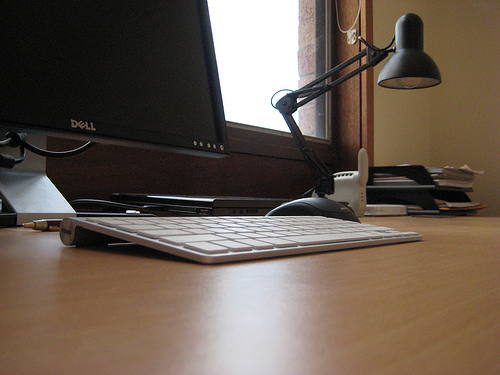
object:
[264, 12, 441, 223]
lamp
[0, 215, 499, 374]
desk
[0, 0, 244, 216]
computer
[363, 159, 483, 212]
rack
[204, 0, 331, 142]
window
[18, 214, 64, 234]
pen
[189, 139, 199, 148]
button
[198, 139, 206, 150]
button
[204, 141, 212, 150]
button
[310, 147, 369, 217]
modem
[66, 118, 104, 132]
dell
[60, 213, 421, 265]
keyboard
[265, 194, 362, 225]
mouse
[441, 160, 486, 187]
paper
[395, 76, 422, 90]
bulb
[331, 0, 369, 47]
string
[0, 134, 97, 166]
wires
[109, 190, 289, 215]
laptop